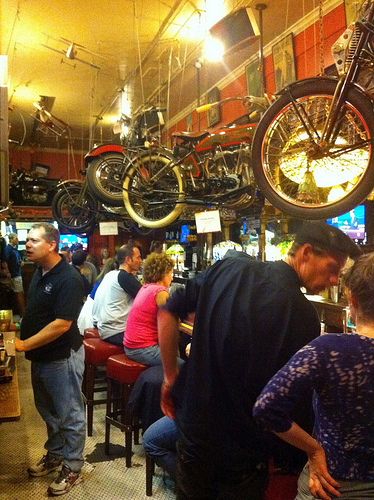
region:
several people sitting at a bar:
[72, 226, 184, 392]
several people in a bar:
[1, 203, 355, 492]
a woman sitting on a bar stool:
[102, 248, 174, 469]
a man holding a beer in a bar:
[4, 231, 24, 317]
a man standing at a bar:
[10, 222, 93, 495]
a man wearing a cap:
[279, 213, 358, 307]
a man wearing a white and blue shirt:
[89, 241, 140, 339]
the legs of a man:
[24, 364, 84, 493]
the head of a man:
[17, 222, 60, 266]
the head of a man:
[291, 215, 355, 299]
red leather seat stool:
[98, 348, 150, 471]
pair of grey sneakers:
[20, 449, 93, 497]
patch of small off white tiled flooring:
[1, 418, 162, 497]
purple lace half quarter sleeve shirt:
[250, 327, 372, 491]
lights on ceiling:
[195, 1, 230, 74]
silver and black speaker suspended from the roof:
[200, 2, 264, 61]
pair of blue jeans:
[21, 341, 97, 476]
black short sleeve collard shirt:
[13, 257, 88, 366]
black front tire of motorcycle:
[253, 73, 373, 223]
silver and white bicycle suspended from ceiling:
[117, 88, 279, 230]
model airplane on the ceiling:
[50, 25, 101, 81]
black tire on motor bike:
[247, 77, 372, 214]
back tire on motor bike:
[121, 149, 189, 227]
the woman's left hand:
[307, 450, 342, 498]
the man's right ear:
[301, 242, 311, 268]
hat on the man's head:
[297, 221, 361, 250]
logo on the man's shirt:
[42, 282, 54, 296]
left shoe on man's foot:
[45, 464, 84, 497]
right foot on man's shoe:
[27, 454, 56, 479]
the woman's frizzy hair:
[142, 253, 169, 283]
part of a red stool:
[103, 352, 144, 462]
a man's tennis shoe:
[48, 466, 87, 496]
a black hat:
[293, 220, 361, 261]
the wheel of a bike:
[237, 84, 368, 218]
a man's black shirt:
[10, 251, 87, 365]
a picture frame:
[268, 31, 297, 90]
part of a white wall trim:
[287, 0, 338, 35]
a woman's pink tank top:
[123, 282, 172, 349]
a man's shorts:
[9, 273, 26, 296]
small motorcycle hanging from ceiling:
[249, 6, 367, 243]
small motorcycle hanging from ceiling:
[121, 94, 296, 241]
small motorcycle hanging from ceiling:
[85, 112, 132, 225]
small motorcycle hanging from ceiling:
[53, 152, 93, 247]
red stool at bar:
[101, 343, 161, 468]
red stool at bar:
[78, 331, 112, 370]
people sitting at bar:
[79, 235, 264, 468]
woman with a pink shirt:
[120, 273, 179, 371]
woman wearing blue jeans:
[123, 335, 183, 376]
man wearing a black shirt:
[168, 243, 310, 468]